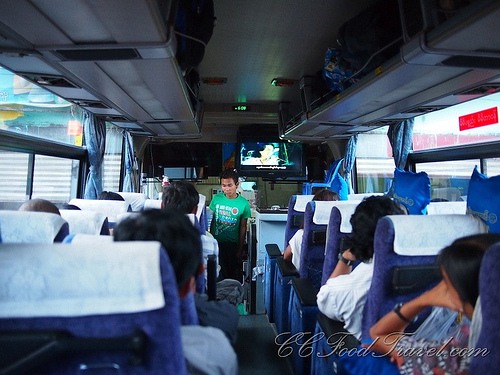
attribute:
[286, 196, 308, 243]
seat — blue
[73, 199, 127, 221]
cloth — white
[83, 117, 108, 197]
curtains — blue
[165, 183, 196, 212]
hair — black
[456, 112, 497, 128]
sticker — red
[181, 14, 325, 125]
ceiling — white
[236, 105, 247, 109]
light — green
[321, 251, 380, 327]
shirt — white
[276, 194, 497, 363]
chairs — blue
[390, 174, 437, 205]
pillows — blue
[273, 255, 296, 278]
armrest — black